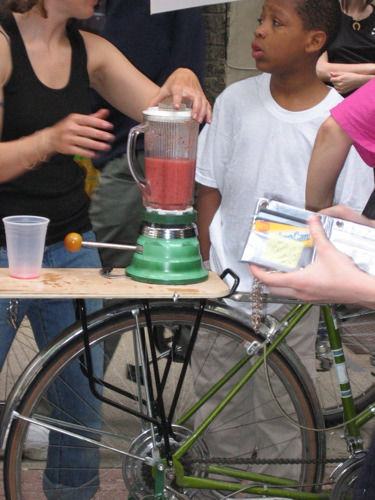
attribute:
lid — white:
[144, 100, 193, 120]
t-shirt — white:
[193, 70, 373, 319]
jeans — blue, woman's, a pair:
[0, 230, 107, 499]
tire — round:
[3, 297, 330, 498]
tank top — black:
[9, 49, 92, 124]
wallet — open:
[238, 189, 370, 300]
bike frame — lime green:
[1, 284, 369, 496]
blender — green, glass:
[121, 101, 212, 284]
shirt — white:
[192, 68, 374, 322]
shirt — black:
[11, 36, 110, 237]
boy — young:
[208, 1, 337, 491]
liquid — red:
[144, 156, 196, 208]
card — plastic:
[252, 218, 318, 246]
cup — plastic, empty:
[3, 213, 51, 279]